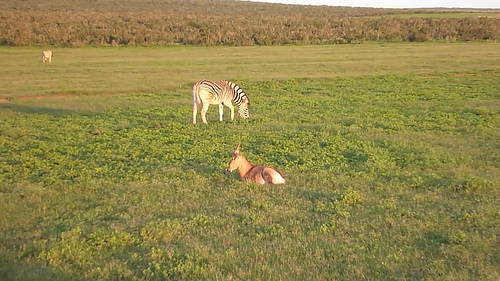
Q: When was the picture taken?
A: Daytime.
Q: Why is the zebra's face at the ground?
A: Eating.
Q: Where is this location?
A: Field.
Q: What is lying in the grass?
A: Deer.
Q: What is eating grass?
A: Zebra.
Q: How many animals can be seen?
A: Three.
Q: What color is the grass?
A: Green.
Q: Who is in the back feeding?
A: Buck.